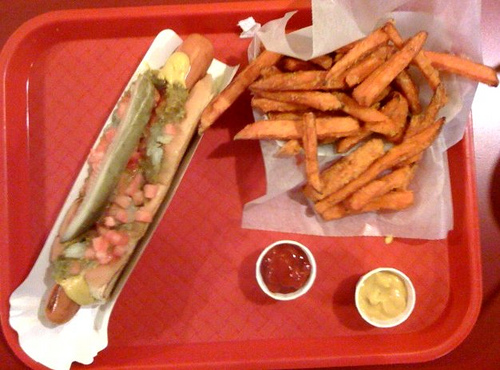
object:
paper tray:
[3, 29, 249, 362]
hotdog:
[49, 34, 217, 326]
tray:
[2, 0, 483, 367]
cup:
[256, 239, 316, 302]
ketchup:
[273, 253, 299, 281]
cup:
[354, 267, 415, 329]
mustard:
[375, 283, 396, 321]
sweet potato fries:
[237, 29, 442, 143]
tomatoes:
[104, 229, 129, 244]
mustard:
[162, 48, 196, 87]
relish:
[165, 89, 187, 120]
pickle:
[57, 81, 156, 241]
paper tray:
[236, 0, 494, 244]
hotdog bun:
[66, 80, 218, 291]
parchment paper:
[307, 1, 483, 151]